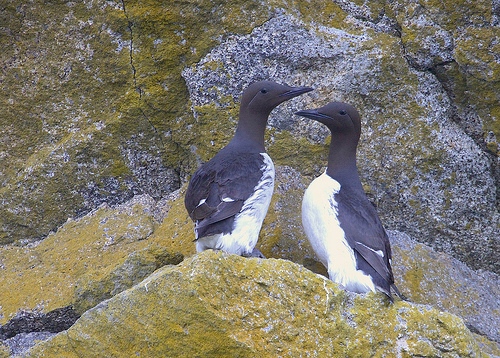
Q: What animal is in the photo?
A: Bird.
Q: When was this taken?
A: Daylight.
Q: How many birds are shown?
A: 2.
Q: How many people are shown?
A: 0.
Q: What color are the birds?
A: Black and white.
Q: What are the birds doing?
A: Standing.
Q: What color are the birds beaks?
A: Black.